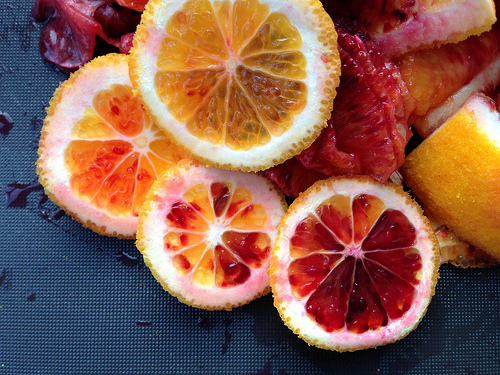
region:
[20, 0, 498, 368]
lemons cut in half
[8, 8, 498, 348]
slices of lemons on a blue surface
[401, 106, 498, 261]
yellow peel of a lemon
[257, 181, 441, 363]
slice of lemon is red an yellow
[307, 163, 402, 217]
yellow part of a lemon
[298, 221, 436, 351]
red part of a lemon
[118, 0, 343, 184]
a half of lemon is yellow and red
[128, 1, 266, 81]
yellow part of a lemon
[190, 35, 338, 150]
yellow and red part of a lemon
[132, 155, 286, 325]
peel of a lemon is yellow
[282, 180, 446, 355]
Orange that has been sliced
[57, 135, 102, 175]
Section of the orange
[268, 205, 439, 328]
Other fruit is staining the orange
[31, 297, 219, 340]
Fruit juice on the tablecloth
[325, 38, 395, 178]
Strawberries that have been sliced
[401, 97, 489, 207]
Peeling of a fruit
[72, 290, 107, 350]
The cloth is textured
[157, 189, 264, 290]
The orange is stained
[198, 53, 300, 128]
Inside of orange has red in it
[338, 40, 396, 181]
The fruit is wrinkled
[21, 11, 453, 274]
this is a picture of promegranets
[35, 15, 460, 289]
these promegranets look messy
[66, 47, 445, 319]
the promegranets look fresh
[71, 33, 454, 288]
these fruits are marroon and orange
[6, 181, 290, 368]
the table cloth is blue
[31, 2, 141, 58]
some kind of chopped fruit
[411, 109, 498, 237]
a promegranet peel on the side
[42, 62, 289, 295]
the rind of the promegranets are purple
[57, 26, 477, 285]
this fruit is probably for display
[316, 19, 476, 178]
this fruit looks chopped up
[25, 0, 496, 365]
halfs of lemons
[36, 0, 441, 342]
halfs of lemons are yellow and red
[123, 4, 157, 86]
peel of lemon is yellow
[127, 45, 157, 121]
a white layer below the yellow peel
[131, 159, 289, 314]
half of lemon is color red and yellow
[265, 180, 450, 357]
lemon is red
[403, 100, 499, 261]
a yellow peel of a lemon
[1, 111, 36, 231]
drops of water on blue table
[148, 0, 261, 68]
yellow part of a lemon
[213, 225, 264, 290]
red part of a lemon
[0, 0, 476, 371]
Sliced fruits on a table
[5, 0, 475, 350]
sliced blood oranges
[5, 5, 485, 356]
Sliced lemons on a blue surface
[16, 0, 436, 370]
Thin slices of a fruit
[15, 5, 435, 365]
Thin lemon slices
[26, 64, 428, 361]
Slices of a fruit soaked and stained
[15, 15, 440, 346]
Fruits stained in juice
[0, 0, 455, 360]
juicy fruits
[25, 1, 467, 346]
A pile of sliced fruit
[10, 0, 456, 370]
lemon slices soaked in juice